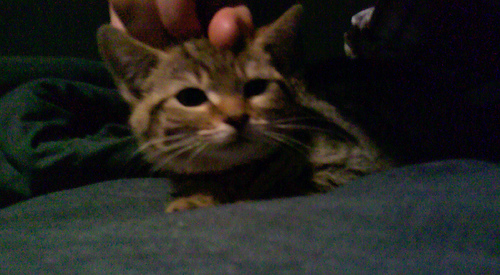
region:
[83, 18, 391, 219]
This is a cat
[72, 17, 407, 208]
Cat is young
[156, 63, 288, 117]
Eyes are black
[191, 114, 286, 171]
White fur around nose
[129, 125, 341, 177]
Whiskers are white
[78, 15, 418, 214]
The fur is black and white and brown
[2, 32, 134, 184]
Green blankets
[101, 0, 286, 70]
The person is white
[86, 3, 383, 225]
a brown cat with black stripes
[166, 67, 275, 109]
eyes of cat are black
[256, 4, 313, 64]
right ear of cat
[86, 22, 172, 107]
right ear of cat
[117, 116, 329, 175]
whiskers of cat are white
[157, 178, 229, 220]
paw of cat below a head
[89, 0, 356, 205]
a hand on head of cat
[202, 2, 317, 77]
a finger next the ear of cat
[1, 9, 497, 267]
a cat over a blue surface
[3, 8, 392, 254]
green fabric on left side of cat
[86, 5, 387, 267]
cat lying on gray cushion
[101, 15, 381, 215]
head turned to the side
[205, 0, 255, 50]
side of thumb on top of cat head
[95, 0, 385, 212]
brown cat with dark eyes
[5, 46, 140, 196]
folded green fabric to side of cat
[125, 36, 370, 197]
darker brown markings across fur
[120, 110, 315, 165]
gray whiskers pointing to sides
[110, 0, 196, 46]
fingers curled by head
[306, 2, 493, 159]
dark space with white points of light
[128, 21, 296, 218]
head elevated over front paw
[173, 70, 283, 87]
Cat has dark eyes.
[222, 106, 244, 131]
Cat has tan nose.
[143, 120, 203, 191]
Cat has white whiskers.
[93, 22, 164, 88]
Cat has tan ear.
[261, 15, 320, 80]
Cat has tan ear.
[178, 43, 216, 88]
Cat has stripe on head.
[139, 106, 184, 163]
Cat has tan cheek.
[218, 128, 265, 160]
Cat has white chin.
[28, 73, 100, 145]
Green blanket near cat.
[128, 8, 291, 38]
Person petting cat's head.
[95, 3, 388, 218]
Hands are caressing a kitties head.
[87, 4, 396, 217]
Cat is lying down.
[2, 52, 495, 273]
The bed has green blankets and pillows.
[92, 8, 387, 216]
The kitten is brown.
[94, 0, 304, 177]
Hand is petting cats head.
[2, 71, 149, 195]
The pillow is wrinkled.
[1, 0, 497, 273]
Cat is lying on a bed.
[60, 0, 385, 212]
Cat is staring to the left.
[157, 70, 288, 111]
Black eyes staring.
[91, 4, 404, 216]
A hand is rubbing a kittens head.